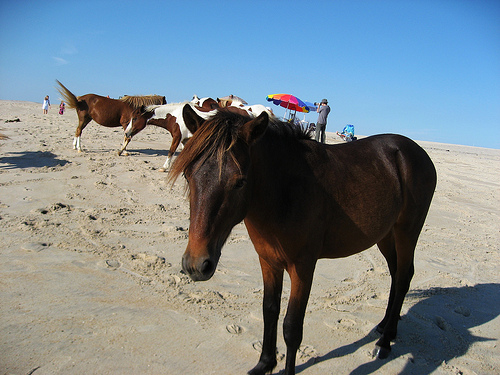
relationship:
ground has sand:
[3, 102, 497, 373] [1, 102, 499, 371]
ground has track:
[3, 102, 497, 373] [53, 203, 67, 213]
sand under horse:
[1, 102, 499, 371] [168, 101, 438, 373]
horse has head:
[168, 101, 438, 373] [166, 101, 269, 280]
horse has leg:
[168, 101, 438, 373] [281, 255, 319, 375]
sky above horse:
[1, 4, 499, 150] [168, 101, 438, 373]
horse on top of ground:
[168, 101, 438, 373] [3, 102, 497, 373]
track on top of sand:
[53, 203, 67, 213] [1, 102, 499, 371]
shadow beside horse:
[0, 151, 71, 172] [55, 80, 167, 154]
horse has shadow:
[168, 101, 438, 373] [279, 281, 499, 373]